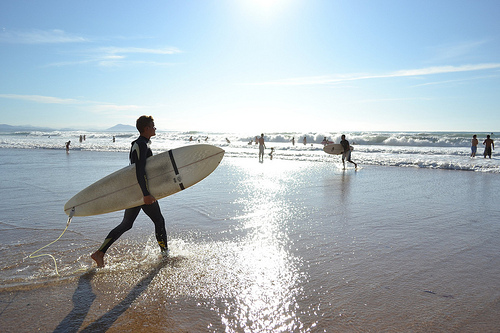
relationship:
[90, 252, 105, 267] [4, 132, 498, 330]
foot on water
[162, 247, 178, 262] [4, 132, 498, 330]
foot on water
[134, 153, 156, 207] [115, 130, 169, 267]
arm in wetsuit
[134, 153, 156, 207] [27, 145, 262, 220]
arm over surfboard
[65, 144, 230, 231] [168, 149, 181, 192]
surfboard has strip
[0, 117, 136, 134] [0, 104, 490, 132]
mountains on horizon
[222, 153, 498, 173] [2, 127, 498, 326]
wave on ocean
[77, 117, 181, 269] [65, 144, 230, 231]
man walking with surfboard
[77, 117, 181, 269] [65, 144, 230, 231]
man carrying surfboard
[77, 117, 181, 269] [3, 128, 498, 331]
man on beach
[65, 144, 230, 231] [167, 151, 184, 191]
surfboard has stripe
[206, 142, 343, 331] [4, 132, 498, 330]
light reflection on water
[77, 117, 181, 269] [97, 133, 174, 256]
man wearing a wetsuit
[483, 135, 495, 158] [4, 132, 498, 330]
person standing in water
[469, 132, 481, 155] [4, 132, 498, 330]
person standing in water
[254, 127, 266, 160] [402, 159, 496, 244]
man on beach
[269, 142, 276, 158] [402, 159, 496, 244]
child on beach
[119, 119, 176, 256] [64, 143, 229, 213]
man carrying surfboard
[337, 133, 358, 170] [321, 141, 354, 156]
man carrying surfboard